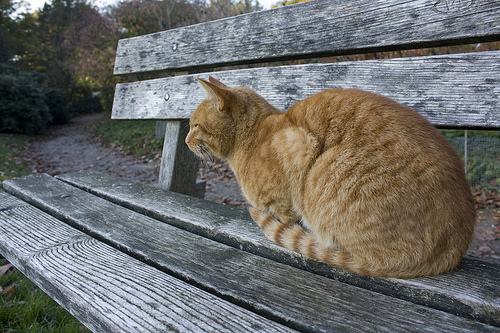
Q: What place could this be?
A: It is a park.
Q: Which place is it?
A: It is a park.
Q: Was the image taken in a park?
A: Yes, it was taken in a park.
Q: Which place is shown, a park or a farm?
A: It is a park.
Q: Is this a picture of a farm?
A: No, the picture is showing a park.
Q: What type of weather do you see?
A: It is sunny.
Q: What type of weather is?
A: It is sunny.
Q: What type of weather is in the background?
A: It is sunny.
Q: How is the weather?
A: It is sunny.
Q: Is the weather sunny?
A: Yes, it is sunny.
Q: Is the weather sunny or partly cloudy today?
A: It is sunny.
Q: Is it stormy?
A: No, it is sunny.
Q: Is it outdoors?
A: Yes, it is outdoors.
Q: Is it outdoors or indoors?
A: It is outdoors.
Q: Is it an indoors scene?
A: No, it is outdoors.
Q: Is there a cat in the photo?
A: Yes, there is a cat.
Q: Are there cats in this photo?
A: Yes, there is a cat.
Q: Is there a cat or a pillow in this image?
A: Yes, there is a cat.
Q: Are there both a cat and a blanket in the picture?
A: No, there is a cat but no blankets.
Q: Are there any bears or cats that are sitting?
A: Yes, the cat is sitting.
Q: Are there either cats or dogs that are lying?
A: Yes, the cat is lying.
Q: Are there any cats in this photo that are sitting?
A: Yes, there is a cat that is sitting.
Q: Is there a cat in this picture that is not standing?
A: Yes, there is a cat that is sitting.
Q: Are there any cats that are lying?
A: Yes, there is a cat that is lying.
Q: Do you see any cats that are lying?
A: Yes, there is a cat that is lying.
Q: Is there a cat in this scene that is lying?
A: Yes, there is a cat that is lying.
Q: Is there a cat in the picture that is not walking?
A: Yes, there is a cat that is lying.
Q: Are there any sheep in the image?
A: No, there are no sheep.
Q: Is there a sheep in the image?
A: No, there is no sheep.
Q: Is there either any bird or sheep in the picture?
A: No, there are no sheep or birds.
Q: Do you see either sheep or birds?
A: No, there are no sheep or birds.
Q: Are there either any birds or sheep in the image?
A: No, there are no sheep or birds.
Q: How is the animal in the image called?
A: The animal is a cat.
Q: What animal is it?
A: The animal is a cat.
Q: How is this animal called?
A: This is a cat.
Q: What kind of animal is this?
A: This is a cat.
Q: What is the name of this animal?
A: This is a cat.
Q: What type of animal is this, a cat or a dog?
A: This is a cat.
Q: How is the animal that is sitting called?
A: The animal is a cat.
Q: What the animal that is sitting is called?
A: The animal is a cat.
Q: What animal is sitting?
A: The animal is a cat.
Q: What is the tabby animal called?
A: The animal is a cat.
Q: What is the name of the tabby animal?
A: The animal is a cat.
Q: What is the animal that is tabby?
A: The animal is a cat.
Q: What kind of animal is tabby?
A: The animal is a cat.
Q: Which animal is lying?
A: The animal is a cat.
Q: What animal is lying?
A: The animal is a cat.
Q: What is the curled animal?
A: The animal is a cat.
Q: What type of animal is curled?
A: The animal is a cat.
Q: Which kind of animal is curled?
A: The animal is a cat.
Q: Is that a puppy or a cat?
A: That is a cat.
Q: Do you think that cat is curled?
A: Yes, the cat is curled.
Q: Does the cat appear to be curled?
A: Yes, the cat is curled.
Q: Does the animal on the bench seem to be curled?
A: Yes, the cat is curled.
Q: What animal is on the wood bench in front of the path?
A: The cat is on the bench.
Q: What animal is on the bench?
A: The cat is on the bench.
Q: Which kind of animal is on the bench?
A: The animal is a cat.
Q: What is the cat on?
A: The cat is on the bench.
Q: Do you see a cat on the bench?
A: Yes, there is a cat on the bench.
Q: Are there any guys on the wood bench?
A: No, there is a cat on the bench.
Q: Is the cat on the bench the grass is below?
A: Yes, the cat is on the bench.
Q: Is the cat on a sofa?
A: No, the cat is on the bench.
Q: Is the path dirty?
A: Yes, the path is dirty.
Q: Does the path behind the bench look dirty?
A: Yes, the path is dirty.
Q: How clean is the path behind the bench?
A: The path is dirty.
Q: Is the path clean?
A: No, the path is dirty.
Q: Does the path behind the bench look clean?
A: No, the path is dirty.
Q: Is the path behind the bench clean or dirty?
A: The path is dirty.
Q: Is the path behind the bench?
A: Yes, the path is behind the bench.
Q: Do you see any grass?
A: Yes, there is grass.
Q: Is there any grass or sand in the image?
A: Yes, there is grass.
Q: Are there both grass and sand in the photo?
A: No, there is grass but no sand.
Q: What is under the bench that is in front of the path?
A: The grass is under the bench.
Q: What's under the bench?
A: The grass is under the bench.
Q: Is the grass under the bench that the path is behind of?
A: Yes, the grass is under the bench.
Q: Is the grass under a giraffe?
A: No, the grass is under the bench.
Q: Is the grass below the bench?
A: Yes, the grass is below the bench.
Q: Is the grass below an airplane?
A: No, the grass is below the bench.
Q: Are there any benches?
A: Yes, there is a bench.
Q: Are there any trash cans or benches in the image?
A: Yes, there is a bench.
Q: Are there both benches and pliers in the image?
A: No, there is a bench but no pliers.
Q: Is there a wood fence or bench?
A: Yes, there is a wood bench.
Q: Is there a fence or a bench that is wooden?
A: Yes, the bench is wooden.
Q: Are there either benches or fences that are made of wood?
A: Yes, the bench is made of wood.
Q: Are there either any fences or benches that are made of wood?
A: Yes, the bench is made of wood.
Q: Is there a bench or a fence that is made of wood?
A: Yes, the bench is made of wood.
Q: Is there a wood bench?
A: Yes, there is a wood bench.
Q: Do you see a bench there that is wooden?
A: Yes, there is a bench that is wooden.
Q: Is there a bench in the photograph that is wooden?
A: Yes, there is a bench that is wooden.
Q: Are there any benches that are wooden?
A: Yes, there is a bench that is wooden.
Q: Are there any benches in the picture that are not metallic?
A: Yes, there is a wooden bench.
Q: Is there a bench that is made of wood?
A: Yes, there is a bench that is made of wood.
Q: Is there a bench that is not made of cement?
A: Yes, there is a bench that is made of wood.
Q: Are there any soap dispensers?
A: No, there are no soap dispensers.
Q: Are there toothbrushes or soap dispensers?
A: No, there are no soap dispensers or toothbrushes.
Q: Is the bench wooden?
A: Yes, the bench is wooden.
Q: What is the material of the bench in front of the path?
A: The bench is made of wood.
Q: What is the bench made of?
A: The bench is made of wood.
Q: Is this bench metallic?
A: No, the bench is wooden.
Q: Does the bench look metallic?
A: No, the bench is wooden.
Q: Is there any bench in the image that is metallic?
A: No, there is a bench but it is wooden.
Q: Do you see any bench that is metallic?
A: No, there is a bench but it is wooden.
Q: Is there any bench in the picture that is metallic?
A: No, there is a bench but it is wooden.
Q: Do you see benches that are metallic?
A: No, there is a bench but it is wooden.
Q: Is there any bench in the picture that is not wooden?
A: No, there is a bench but it is wooden.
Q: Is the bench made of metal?
A: No, the bench is made of wood.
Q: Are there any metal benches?
A: No, there is a bench but it is made of wood.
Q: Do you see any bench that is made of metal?
A: No, there is a bench but it is made of wood.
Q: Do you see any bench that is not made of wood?
A: No, there is a bench but it is made of wood.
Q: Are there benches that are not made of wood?
A: No, there is a bench but it is made of wood.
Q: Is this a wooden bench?
A: Yes, this is a wooden bench.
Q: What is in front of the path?
A: The bench is in front of the path.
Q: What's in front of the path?
A: The bench is in front of the path.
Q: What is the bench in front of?
A: The bench is in front of the path.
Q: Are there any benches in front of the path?
A: Yes, there is a bench in front of the path.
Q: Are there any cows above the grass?
A: No, there is a bench above the grass.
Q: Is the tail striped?
A: Yes, the tail is striped.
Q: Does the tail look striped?
A: Yes, the tail is striped.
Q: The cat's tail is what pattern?
A: The tail is striped.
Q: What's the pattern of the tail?
A: The tail is striped.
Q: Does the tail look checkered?
A: No, the tail is striped.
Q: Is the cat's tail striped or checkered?
A: The tail is striped.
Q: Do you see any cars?
A: No, there are no cars.